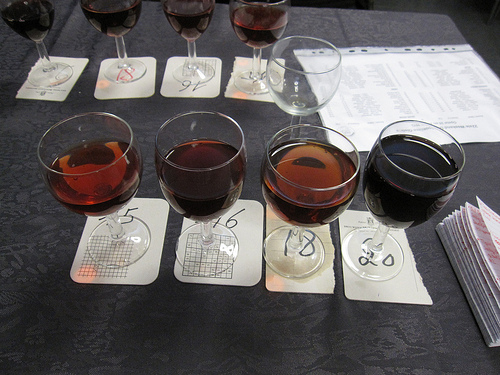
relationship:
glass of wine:
[364, 123, 466, 296] [384, 137, 452, 189]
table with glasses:
[1, 0, 498, 373] [2, 2, 465, 279]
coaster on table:
[336, 206, 433, 306] [1, 0, 498, 373]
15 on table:
[98, 204, 140, 228] [1, 0, 498, 373]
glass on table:
[261, 123, 363, 284] [1, 0, 498, 373]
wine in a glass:
[48, 141, 138, 217] [33, 103, 158, 273]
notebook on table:
[435, 193, 499, 344] [1, 0, 498, 373]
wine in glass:
[154, 134, 244, 224] [261, 123, 363, 284]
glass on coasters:
[261, 123, 363, 284] [70, 197, 432, 307]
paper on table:
[297, 36, 498, 146] [1, 0, 498, 373]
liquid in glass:
[364, 133, 457, 229] [340, 118, 462, 281]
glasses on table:
[47, 79, 457, 294] [1, 0, 498, 373]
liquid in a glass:
[46, 135, 141, 218] [33, 103, 158, 273]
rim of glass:
[378, 119, 466, 180] [340, 118, 462, 281]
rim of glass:
[266, 123, 359, 190] [261, 123, 363, 284]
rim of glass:
[151, 110, 243, 173] [156, 110, 244, 275]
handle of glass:
[116, 35, 128, 69] [83, 3, 144, 81]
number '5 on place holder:
[116, 202, 138, 226] [68, 195, 168, 285]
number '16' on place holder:
[208, 203, 248, 229] [323, 206, 436, 311]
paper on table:
[289, 43, 497, 153] [1, 0, 498, 373]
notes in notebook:
[457, 206, 498, 269] [433, 185, 498, 350]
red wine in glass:
[363, 138, 454, 224] [340, 118, 462, 281]